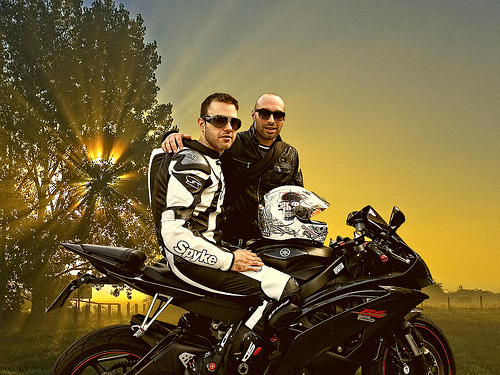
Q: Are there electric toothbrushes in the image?
A: No, there are no electric toothbrushes.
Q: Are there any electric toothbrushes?
A: No, there are no electric toothbrushes.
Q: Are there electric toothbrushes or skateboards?
A: No, there are no electric toothbrushes or skateboards.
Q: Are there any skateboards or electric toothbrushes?
A: No, there are no electric toothbrushes or skateboards.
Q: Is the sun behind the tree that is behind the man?
A: Yes, the sun is behind the tree.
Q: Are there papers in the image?
A: No, there are no papers.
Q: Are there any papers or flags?
A: No, there are no papers or flags.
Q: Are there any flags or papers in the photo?
A: No, there are no papers or flags.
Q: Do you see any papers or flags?
A: No, there are no papers or flags.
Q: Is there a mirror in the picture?
A: Yes, there is a mirror.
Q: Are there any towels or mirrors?
A: Yes, there is a mirror.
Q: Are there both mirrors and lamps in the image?
A: No, there is a mirror but no lamps.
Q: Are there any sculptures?
A: No, there are no sculptures.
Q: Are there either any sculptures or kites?
A: No, there are no sculptures or kites.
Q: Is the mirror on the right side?
A: Yes, the mirror is on the right of the image.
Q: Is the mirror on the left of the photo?
A: No, the mirror is on the right of the image.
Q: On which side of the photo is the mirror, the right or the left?
A: The mirror is on the right of the image.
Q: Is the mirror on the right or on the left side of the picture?
A: The mirror is on the right of the image.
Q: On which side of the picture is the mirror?
A: The mirror is on the right of the image.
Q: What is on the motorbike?
A: The mirror is on the motorbike.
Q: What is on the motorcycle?
A: The mirror is on the motorbike.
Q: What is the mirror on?
A: The mirror is on the motorcycle.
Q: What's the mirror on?
A: The mirror is on the motorcycle.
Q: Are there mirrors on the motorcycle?
A: Yes, there is a mirror on the motorcycle.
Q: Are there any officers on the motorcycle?
A: No, there is a mirror on the motorcycle.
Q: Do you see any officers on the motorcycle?
A: No, there is a mirror on the motorcycle.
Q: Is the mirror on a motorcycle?
A: Yes, the mirror is on a motorcycle.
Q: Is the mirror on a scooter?
A: No, the mirror is on a motorcycle.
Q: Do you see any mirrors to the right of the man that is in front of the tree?
A: Yes, there is a mirror to the right of the man.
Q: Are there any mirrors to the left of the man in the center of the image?
A: No, the mirror is to the right of the man.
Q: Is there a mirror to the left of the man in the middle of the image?
A: No, the mirror is to the right of the man.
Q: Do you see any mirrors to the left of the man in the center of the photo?
A: No, the mirror is to the right of the man.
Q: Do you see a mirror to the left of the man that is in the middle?
A: No, the mirror is to the right of the man.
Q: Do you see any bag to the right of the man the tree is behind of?
A: No, there is a mirror to the right of the man.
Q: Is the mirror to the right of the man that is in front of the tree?
A: Yes, the mirror is to the right of the man.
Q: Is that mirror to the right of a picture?
A: No, the mirror is to the right of the man.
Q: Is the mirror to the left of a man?
A: No, the mirror is to the right of a man.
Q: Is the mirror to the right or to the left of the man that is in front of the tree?
A: The mirror is to the right of the man.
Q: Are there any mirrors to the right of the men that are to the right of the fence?
A: Yes, there is a mirror to the right of the men.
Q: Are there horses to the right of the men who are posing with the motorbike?
A: No, there is a mirror to the right of the men.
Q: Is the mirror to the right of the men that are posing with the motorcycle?
A: Yes, the mirror is to the right of the men.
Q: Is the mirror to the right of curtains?
A: No, the mirror is to the right of the men.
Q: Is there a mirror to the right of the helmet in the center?
A: Yes, there is a mirror to the right of the helmet.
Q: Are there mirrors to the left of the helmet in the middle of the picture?
A: No, the mirror is to the right of the helmet.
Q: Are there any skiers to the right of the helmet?
A: No, there is a mirror to the right of the helmet.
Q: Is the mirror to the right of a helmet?
A: Yes, the mirror is to the right of a helmet.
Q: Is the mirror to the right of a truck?
A: No, the mirror is to the right of a helmet.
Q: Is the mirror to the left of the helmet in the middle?
A: No, the mirror is to the right of the helmet.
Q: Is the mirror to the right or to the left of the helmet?
A: The mirror is to the right of the helmet.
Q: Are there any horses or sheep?
A: No, there are no horses or sheep.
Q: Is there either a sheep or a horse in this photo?
A: No, there are no horses or sheep.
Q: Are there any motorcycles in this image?
A: Yes, there is a motorcycle.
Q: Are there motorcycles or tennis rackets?
A: Yes, there is a motorcycle.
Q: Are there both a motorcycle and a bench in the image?
A: No, there is a motorcycle but no benches.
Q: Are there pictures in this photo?
A: No, there are no pictures.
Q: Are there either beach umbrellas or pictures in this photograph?
A: No, there are no pictures or beach umbrellas.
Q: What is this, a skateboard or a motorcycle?
A: This is a motorcycle.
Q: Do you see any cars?
A: No, there are no cars.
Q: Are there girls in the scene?
A: No, there are no girls.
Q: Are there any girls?
A: No, there are no girls.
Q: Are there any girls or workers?
A: No, there are no girls or workers.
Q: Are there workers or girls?
A: No, there are no girls or workers.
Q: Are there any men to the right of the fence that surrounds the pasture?
A: Yes, there are men to the right of the fence.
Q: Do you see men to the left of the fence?
A: No, the men are to the right of the fence.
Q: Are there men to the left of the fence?
A: No, the men are to the right of the fence.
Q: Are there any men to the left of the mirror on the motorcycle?
A: Yes, there are men to the left of the mirror.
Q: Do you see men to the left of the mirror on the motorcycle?
A: Yes, there are men to the left of the mirror.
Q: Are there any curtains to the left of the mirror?
A: No, there are men to the left of the mirror.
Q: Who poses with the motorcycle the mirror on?
A: The men pose with the motorcycle.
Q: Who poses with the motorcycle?
A: The men pose with the motorcycle.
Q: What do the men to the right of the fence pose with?
A: The men pose with the motorcycle.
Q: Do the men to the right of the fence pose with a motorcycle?
A: Yes, the men pose with a motorcycle.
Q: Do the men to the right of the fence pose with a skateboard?
A: No, the men pose with a motorcycle.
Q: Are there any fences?
A: Yes, there is a fence.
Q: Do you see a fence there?
A: Yes, there is a fence.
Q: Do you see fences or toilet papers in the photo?
A: Yes, there is a fence.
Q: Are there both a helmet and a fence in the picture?
A: Yes, there are both a fence and a helmet.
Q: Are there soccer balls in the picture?
A: No, there are no soccer balls.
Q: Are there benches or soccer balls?
A: No, there are no soccer balls or benches.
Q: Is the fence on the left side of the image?
A: Yes, the fence is on the left of the image.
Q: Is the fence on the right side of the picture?
A: No, the fence is on the left of the image.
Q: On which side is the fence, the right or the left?
A: The fence is on the left of the image.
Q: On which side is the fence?
A: The fence is on the left of the image.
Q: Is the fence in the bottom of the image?
A: Yes, the fence is in the bottom of the image.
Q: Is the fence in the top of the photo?
A: No, the fence is in the bottom of the image.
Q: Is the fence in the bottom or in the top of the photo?
A: The fence is in the bottom of the image.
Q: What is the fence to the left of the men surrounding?
A: The fence is surrounding the pasture.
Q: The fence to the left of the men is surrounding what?
A: The fence is surrounding the pasture.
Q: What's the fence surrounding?
A: The fence is surrounding the pasture.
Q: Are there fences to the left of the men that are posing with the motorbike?
A: Yes, there is a fence to the left of the men.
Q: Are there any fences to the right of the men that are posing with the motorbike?
A: No, the fence is to the left of the men.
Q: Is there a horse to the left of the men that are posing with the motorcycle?
A: No, there is a fence to the left of the men.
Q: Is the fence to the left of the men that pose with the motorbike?
A: Yes, the fence is to the left of the men.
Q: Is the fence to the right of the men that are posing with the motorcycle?
A: No, the fence is to the left of the men.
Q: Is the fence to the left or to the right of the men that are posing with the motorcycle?
A: The fence is to the left of the men.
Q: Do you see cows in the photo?
A: Yes, there is a cow.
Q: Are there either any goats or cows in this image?
A: Yes, there is a cow.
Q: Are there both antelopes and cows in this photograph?
A: No, there is a cow but no antelopes.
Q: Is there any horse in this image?
A: No, there are no horses.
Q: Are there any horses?
A: No, there are no horses.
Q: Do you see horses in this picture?
A: No, there are no horses.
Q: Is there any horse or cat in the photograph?
A: No, there are no horses or cats.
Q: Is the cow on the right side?
A: Yes, the cow is on the right of the image.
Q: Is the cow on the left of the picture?
A: No, the cow is on the right of the image.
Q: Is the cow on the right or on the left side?
A: The cow is on the right of the image.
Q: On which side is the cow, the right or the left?
A: The cow is on the right of the image.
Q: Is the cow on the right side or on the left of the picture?
A: The cow is on the right of the image.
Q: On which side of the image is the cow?
A: The cow is on the right of the image.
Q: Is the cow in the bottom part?
A: Yes, the cow is in the bottom of the image.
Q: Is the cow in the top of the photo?
A: No, the cow is in the bottom of the image.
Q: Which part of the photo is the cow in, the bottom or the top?
A: The cow is in the bottom of the image.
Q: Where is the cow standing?
A: The cow is standing in the pasture.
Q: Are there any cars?
A: No, there are no cars.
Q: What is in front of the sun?
A: The tree is in front of the sun.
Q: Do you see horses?
A: No, there are no horses.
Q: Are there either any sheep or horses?
A: No, there are no horses or sheep.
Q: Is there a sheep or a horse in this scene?
A: No, there are no horses or sheep.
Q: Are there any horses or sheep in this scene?
A: No, there are no horses or sheep.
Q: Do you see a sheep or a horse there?
A: No, there are no horses or sheep.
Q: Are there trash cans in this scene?
A: No, there are no trash cans.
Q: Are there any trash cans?
A: No, there are no trash cans.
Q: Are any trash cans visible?
A: No, there are no trash cans.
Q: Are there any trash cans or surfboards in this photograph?
A: No, there are no trash cans or surfboards.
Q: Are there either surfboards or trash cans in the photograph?
A: No, there are no trash cans or surfboards.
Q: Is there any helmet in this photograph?
A: Yes, there is a helmet.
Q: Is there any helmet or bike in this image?
A: Yes, there is a helmet.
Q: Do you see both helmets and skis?
A: No, there is a helmet but no skis.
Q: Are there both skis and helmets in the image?
A: No, there is a helmet but no skis.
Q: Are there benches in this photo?
A: No, there are no benches.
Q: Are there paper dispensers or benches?
A: No, there are no benches or paper dispensers.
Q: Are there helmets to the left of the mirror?
A: Yes, there is a helmet to the left of the mirror.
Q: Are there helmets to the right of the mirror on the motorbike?
A: No, the helmet is to the left of the mirror.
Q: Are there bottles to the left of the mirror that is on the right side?
A: No, there is a helmet to the left of the mirror.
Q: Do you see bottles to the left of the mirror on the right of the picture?
A: No, there is a helmet to the left of the mirror.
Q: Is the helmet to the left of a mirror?
A: Yes, the helmet is to the left of a mirror.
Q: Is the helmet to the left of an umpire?
A: No, the helmet is to the left of a mirror.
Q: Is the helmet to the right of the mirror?
A: No, the helmet is to the left of the mirror.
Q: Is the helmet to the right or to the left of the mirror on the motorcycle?
A: The helmet is to the left of the mirror.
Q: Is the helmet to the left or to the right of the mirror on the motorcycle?
A: The helmet is to the left of the mirror.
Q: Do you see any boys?
A: No, there are no boys.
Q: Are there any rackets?
A: No, there are no rackets.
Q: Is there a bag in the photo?
A: No, there are no bags.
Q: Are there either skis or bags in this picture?
A: No, there are no bags or skis.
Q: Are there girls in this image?
A: No, there are no girls.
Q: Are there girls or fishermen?
A: No, there are no girls or fishermen.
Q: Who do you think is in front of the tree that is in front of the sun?
A: The man is in front of the tree.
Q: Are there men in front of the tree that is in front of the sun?
A: Yes, there is a man in front of the tree.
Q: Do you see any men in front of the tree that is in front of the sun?
A: Yes, there is a man in front of the tree.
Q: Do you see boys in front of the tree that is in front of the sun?
A: No, there is a man in front of the tree.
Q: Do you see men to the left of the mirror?
A: Yes, there is a man to the left of the mirror.